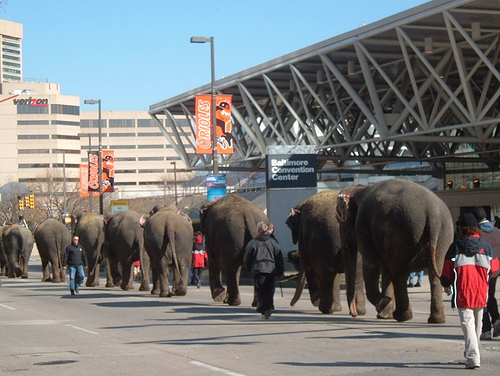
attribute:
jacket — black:
[65, 244, 88, 268]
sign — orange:
[190, 92, 237, 154]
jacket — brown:
[468, 221, 497, 271]